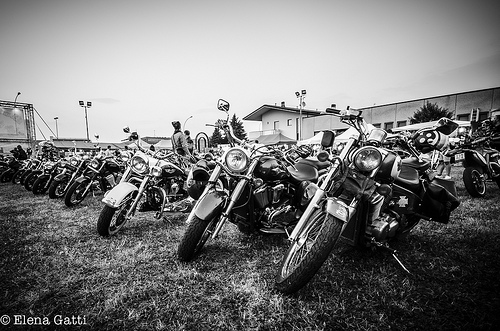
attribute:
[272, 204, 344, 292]
wheel — parked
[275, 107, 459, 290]
motorcycle — parked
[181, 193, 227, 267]
wheel — parked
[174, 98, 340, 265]
motorcycle — parked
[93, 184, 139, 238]
wheel — parked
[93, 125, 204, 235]
motorcycle — parked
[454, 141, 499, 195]
motorcycle — parked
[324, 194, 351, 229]
fender — white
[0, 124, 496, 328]
grass — short, scruffy, dry-looking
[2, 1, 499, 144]
sky — white, cloudy, somber, overcast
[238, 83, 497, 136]
building — white, long, low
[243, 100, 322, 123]
roof — flat